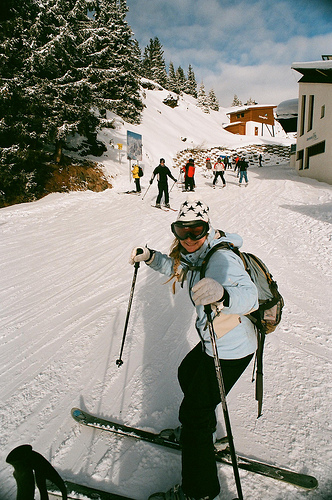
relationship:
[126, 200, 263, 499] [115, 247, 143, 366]
lady holding rod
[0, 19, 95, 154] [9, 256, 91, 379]
tree covered snow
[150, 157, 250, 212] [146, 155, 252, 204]
people are skiing skiing people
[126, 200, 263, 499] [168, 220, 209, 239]
lady has googles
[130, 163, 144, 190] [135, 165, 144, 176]
person carrying backpack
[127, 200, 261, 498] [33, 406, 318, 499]
lady on skis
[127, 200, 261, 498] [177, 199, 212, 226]
lady wearing cap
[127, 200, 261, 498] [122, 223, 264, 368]
lady wearing blue coat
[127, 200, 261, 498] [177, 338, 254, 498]
lady wearing pants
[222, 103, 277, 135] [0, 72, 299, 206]
lodge on hill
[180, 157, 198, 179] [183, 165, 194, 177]
skier in jacket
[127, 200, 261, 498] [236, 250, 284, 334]
lady has backpack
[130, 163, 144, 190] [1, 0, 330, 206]
person in background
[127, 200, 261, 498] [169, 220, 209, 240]
lady wears goggles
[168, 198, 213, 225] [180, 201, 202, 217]
cap has stars